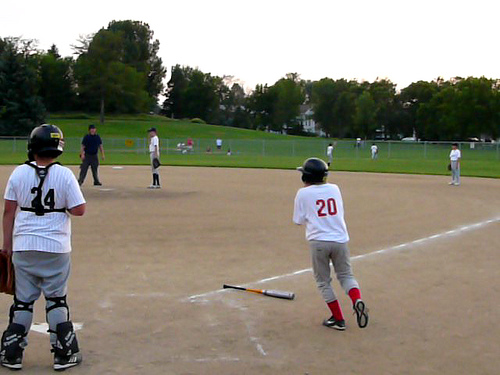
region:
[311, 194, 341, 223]
Number 20 on back of a shirt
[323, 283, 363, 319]
A pair of red socks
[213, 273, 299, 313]
Baseball bat on the dirt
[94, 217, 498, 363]
White lines on the dirt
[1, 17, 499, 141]
Many trees with green leaves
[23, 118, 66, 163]
Helmet on boy's head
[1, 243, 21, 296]
A brown leather glove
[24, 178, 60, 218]
The number 24 on back of shirt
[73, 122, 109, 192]
An umpire on the field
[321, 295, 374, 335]
A pair of sneakers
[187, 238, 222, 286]
part of a ground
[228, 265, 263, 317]
part of a hjandle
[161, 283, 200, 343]
part of a groinmd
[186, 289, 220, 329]
part of a ground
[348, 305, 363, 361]
par of a shoe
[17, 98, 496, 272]
small children playing baseball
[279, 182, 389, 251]
white shirt on baseball player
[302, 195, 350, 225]
red twenty on white shirt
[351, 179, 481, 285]
white line painted on ground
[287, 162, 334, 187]
black helmet on player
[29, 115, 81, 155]
black helmet on player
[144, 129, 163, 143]
black baseball cap on man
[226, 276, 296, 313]
baseball bat on clay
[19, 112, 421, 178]
trimmed green grass in park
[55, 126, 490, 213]
fence around baseball field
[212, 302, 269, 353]
white chalk lines on field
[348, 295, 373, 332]
pattern on bottom of sneakers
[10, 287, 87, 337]
knee pads around boy's knee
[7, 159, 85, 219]
chest mask around boy's chest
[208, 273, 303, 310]
baseball bat on field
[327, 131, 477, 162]
large gray chain link fence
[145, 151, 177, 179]
black bat in man's hand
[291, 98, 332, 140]
large brown and white building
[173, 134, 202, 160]
people sitting on the chairs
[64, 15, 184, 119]
extra tall green tree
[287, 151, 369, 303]
this is a baseball player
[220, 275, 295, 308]
this is a bat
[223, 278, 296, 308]
the bat is on the ground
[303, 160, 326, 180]
this is a helmet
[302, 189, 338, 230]
the jersey is white in color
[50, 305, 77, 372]
he is wearing guards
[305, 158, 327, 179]
the helmet is black in color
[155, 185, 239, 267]
the ground is brown in color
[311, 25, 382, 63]
the sun is setting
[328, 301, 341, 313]
the socks is red in color